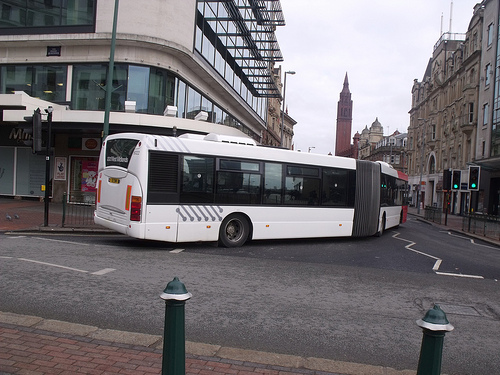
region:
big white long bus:
[80, 140, 422, 235]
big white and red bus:
[100, 140, 410, 245]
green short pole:
[140, 271, 210, 371]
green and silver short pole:
[150, 276, 203, 372]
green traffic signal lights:
[445, 160, 485, 195]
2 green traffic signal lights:
[435, 166, 480, 193]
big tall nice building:
[400, 22, 497, 207]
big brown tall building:
[402, 26, 497, 196]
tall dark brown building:
[322, 75, 367, 155]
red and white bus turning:
[93, 135, 426, 244]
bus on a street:
[83, 126, 416, 256]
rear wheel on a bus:
[216, 210, 256, 254]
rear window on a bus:
[103, 134, 143, 173]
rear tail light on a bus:
[124, 192, 146, 229]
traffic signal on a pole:
[465, 162, 483, 195]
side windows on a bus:
[143, 145, 357, 213]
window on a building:
[478, 98, 493, 130]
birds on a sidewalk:
[1, 208, 25, 225]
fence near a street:
[418, 202, 444, 229]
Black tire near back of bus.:
[214, 210, 273, 276]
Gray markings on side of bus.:
[171, 204, 233, 229]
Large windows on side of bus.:
[194, 154, 356, 202]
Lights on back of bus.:
[84, 183, 162, 227]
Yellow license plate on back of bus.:
[104, 173, 126, 188]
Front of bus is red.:
[390, 173, 422, 237]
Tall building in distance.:
[331, 73, 361, 148]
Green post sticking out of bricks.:
[163, 280, 200, 369]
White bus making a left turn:
[92, 128, 412, 249]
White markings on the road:
[387, 226, 487, 279]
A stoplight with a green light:
[466, 164, 481, 192]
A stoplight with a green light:
[450, 167, 462, 192]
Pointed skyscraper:
[332, 71, 352, 154]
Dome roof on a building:
[370, 117, 383, 127]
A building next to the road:
[406, 10, 483, 218]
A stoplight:
[20, 103, 53, 228]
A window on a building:
[123, 62, 150, 115]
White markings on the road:
[0, 253, 117, 278]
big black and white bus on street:
[94, 131, 411, 243]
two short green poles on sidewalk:
[154, 274, 444, 374]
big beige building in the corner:
[2, 3, 282, 210]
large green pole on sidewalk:
[101, 3, 118, 141]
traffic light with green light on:
[449, 167, 482, 224]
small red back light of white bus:
[127, 193, 142, 224]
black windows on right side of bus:
[144, 152, 420, 205]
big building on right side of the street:
[403, 1, 499, 221]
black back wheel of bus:
[220, 209, 252, 246]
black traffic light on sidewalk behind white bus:
[24, 106, 56, 225]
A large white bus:
[103, 120, 410, 245]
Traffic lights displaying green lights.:
[439, 163, 484, 192]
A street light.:
[278, 65, 303, 142]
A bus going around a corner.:
[82, 125, 429, 267]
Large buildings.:
[9, 5, 498, 267]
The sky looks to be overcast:
[272, 0, 480, 158]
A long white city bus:
[85, 122, 415, 252]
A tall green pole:
[95, 0, 130, 140]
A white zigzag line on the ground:
[386, 216, 486, 282]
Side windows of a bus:
[175, 150, 360, 215]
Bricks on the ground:
[0, 315, 340, 370]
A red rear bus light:
[121, 187, 146, 224]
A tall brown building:
[330, 65, 360, 155]